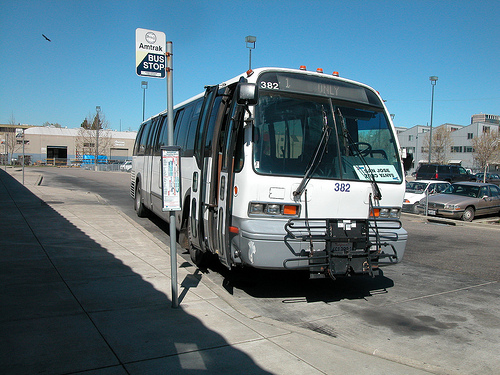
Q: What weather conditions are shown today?
A: It is clear.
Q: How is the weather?
A: It is clear.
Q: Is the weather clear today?
A: Yes, it is clear.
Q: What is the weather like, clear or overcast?
A: It is clear.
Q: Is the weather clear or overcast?
A: It is clear.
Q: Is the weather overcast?
A: No, it is clear.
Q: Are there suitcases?
A: No, there are no suitcases.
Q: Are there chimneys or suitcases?
A: No, there are no suitcases or chimneys.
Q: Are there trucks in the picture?
A: No, there are no trucks.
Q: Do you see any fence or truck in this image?
A: No, there are no trucks or fences.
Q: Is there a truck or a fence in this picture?
A: No, there are no trucks or fences.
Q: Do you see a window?
A: Yes, there are windows.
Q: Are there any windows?
A: Yes, there are windows.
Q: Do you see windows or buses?
A: Yes, there are windows.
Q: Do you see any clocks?
A: No, there are no clocks.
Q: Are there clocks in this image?
A: No, there are no clocks.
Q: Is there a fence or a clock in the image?
A: No, there are no clocks or fences.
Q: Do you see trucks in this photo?
A: No, there are no trucks.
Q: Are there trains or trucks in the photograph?
A: No, there are no trucks or trains.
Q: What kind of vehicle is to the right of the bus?
A: The vehicle is a car.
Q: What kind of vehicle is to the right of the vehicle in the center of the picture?
A: The vehicle is a car.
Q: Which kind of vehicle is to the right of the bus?
A: The vehicle is a car.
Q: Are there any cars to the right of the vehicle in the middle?
A: Yes, there is a car to the right of the bus.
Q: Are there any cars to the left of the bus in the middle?
A: No, the car is to the right of the bus.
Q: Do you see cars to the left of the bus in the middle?
A: No, the car is to the right of the bus.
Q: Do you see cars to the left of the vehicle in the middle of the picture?
A: No, the car is to the right of the bus.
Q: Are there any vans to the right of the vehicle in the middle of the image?
A: No, there is a car to the right of the bus.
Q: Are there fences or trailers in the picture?
A: No, there are no fences or trailers.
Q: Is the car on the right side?
A: Yes, the car is on the right of the image.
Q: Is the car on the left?
A: No, the car is on the right of the image.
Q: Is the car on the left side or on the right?
A: The car is on the right of the image.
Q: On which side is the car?
A: The car is on the right of the image.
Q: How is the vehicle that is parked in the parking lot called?
A: The vehicle is a car.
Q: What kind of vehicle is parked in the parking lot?
A: The vehicle is a car.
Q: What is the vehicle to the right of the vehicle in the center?
A: The vehicle is a car.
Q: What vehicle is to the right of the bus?
A: The vehicle is a car.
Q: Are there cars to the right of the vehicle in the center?
A: Yes, there is a car to the right of the bus.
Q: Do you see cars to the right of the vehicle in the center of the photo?
A: Yes, there is a car to the right of the bus.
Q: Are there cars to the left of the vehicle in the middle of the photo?
A: No, the car is to the right of the bus.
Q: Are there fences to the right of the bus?
A: No, there is a car to the right of the bus.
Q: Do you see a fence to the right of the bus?
A: No, there is a car to the right of the bus.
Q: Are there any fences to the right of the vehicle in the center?
A: No, there is a car to the right of the bus.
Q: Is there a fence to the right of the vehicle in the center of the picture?
A: No, there is a car to the right of the bus.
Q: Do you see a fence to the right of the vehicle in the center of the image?
A: No, there is a car to the right of the bus.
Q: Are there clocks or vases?
A: No, there are no clocks or vases.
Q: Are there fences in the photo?
A: No, there are no fences.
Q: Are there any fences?
A: No, there are no fences.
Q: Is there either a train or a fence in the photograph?
A: No, there are no fences or trains.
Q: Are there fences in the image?
A: No, there are no fences.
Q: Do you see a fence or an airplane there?
A: No, there are no fences or airplanes.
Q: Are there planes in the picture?
A: No, there are no planes.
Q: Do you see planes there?
A: No, there are no planes.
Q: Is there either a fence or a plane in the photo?
A: No, there are no airplanes or fences.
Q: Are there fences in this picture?
A: No, there are no fences.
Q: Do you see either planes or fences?
A: No, there are no fences or planes.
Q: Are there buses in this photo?
A: Yes, there is a bus.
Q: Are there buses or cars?
A: Yes, there is a bus.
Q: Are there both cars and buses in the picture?
A: Yes, there are both a bus and a car.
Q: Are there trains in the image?
A: No, there are no trains.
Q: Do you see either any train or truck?
A: No, there are no trains or trucks.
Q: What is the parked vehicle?
A: The vehicle is a bus.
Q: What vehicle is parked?
A: The vehicle is a bus.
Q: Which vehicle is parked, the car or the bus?
A: The bus is parked.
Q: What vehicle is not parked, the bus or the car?
A: The car is not parked.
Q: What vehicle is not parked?
A: The vehicle is a car.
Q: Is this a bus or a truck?
A: This is a bus.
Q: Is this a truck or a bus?
A: This is a bus.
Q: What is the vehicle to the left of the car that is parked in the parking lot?
A: The vehicle is a bus.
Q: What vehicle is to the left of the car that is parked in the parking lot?
A: The vehicle is a bus.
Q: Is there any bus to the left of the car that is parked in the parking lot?
A: Yes, there is a bus to the left of the car.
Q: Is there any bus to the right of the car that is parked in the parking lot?
A: No, the bus is to the left of the car.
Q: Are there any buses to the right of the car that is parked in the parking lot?
A: No, the bus is to the left of the car.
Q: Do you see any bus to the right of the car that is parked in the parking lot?
A: No, the bus is to the left of the car.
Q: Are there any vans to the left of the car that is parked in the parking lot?
A: No, there is a bus to the left of the car.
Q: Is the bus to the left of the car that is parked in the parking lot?
A: Yes, the bus is to the left of the car.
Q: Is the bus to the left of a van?
A: No, the bus is to the left of the car.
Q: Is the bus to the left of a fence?
A: No, the bus is to the left of the car.